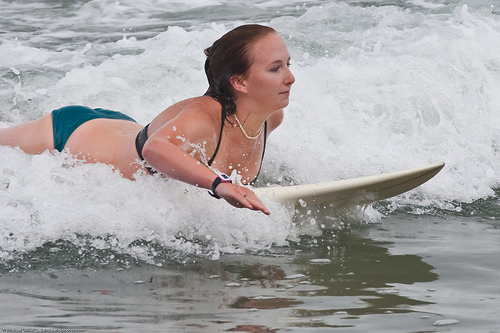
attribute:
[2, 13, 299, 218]
woman — surfboarding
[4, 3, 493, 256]
waves — nice, calm, foamy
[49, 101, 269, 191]
bikini — blue, black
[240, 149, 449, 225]
surfboard — white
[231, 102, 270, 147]
necklace — gold, white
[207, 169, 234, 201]
watch — waterproof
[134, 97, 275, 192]
top — blue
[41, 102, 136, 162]
bottoms — blue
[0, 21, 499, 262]
foam — white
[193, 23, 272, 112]
hair — long, wet, red